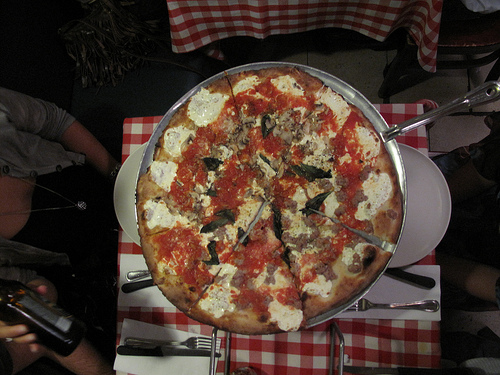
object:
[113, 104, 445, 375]
cloth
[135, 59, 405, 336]
cup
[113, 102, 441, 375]
chair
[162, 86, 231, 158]
melted cheese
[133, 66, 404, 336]
pizza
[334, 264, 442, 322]
napkin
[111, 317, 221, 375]
napkin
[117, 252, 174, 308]
napkin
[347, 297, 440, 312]
fork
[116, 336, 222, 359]
fork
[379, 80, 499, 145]
silverware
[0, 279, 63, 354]
hand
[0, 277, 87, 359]
beer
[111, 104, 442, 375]
table cloth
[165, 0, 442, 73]
table cloth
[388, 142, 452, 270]
plate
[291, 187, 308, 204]
cheese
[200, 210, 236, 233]
mushroom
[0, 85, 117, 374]
person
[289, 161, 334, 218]
spinach